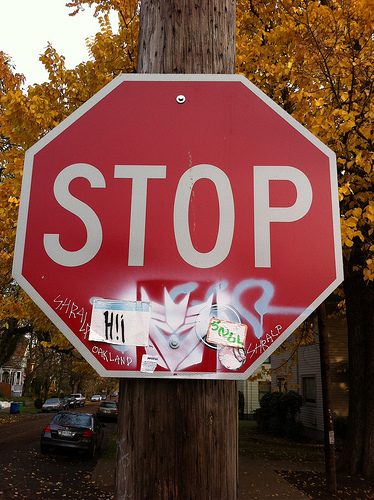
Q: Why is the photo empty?
A: There is no one.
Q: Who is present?
A: Nobody.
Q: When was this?
A: Daytime.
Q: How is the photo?
A: Clear.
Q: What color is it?
A: Red.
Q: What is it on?
A: A post.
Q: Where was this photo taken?
A: At an intersection.